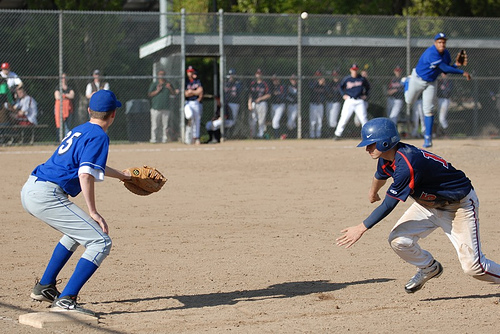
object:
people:
[0, 53, 39, 148]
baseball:
[4, 3, 497, 334]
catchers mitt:
[119, 164, 168, 199]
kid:
[246, 71, 272, 139]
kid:
[305, 67, 331, 140]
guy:
[146, 67, 180, 144]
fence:
[3, 11, 500, 141]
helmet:
[356, 117, 401, 152]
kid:
[337, 117, 500, 295]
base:
[19, 307, 104, 328]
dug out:
[145, 33, 471, 136]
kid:
[17, 88, 163, 316]